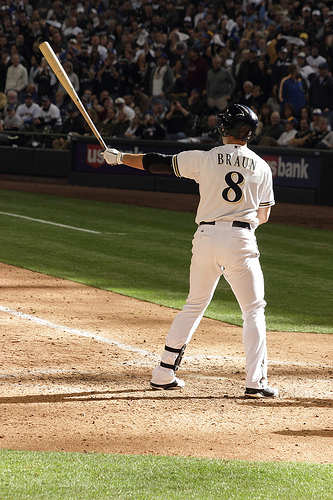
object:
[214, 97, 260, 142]
head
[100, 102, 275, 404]
man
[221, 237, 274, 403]
leg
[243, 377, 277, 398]
shoe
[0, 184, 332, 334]
grass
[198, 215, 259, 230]
belt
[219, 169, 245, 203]
number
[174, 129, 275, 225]
shirt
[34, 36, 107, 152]
baseball bat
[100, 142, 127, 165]
glove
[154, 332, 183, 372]
shin guard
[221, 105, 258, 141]
helmet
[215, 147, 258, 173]
braun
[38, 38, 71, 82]
bat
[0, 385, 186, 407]
shadow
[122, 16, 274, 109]
crowd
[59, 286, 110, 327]
dirt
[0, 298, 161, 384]
line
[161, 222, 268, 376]
white pants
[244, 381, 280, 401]
foot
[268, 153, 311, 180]
logo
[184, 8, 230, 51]
shade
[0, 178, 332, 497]
field